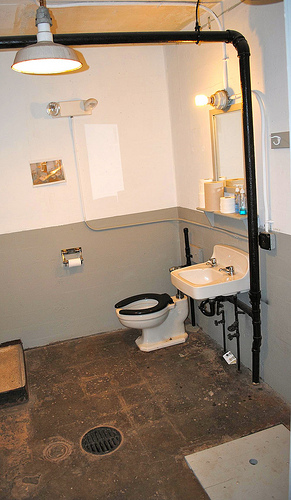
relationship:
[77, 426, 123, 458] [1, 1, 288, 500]
drain in bathroom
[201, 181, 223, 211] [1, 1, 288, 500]
paper towels in bathroom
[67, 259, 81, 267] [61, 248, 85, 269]
toilet paper on holder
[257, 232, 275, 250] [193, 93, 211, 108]
switch for light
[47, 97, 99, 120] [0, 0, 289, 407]
lights on wall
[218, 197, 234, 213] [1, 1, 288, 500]
toilet paper in bathroom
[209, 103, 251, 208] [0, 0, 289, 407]
mirror on wall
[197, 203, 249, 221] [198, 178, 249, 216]
shelf for supplies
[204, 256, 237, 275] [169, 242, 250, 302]
faucet fixtures on sink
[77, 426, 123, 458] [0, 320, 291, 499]
drain on floor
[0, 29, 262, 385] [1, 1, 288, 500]
piping in bathroom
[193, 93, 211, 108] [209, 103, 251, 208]
light above mirror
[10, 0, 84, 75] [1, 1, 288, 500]
lamp in bathroom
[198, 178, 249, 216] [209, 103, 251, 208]
supplies before mirror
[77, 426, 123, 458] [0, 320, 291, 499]
drain in floor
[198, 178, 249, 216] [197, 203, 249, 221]
supplies on shelf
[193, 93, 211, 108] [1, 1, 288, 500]
light fixture in bathroom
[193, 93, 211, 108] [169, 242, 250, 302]
light above sink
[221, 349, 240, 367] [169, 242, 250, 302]
paper under sink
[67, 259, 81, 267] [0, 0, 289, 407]
toilet paper on wall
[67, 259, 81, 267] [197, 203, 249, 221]
toilet paper on shelf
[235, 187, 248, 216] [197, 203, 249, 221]
soap dispenser on shelf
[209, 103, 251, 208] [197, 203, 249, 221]
mirror above shelf